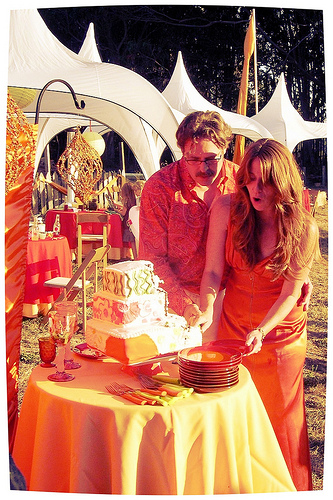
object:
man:
[134, 106, 243, 334]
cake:
[82, 257, 203, 369]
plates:
[176, 347, 244, 366]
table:
[6, 344, 298, 490]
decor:
[0, 134, 67, 181]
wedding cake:
[82, 258, 204, 370]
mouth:
[253, 197, 264, 204]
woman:
[188, 134, 316, 496]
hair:
[229, 138, 322, 278]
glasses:
[179, 153, 223, 170]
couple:
[132, 108, 312, 498]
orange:
[230, 271, 258, 307]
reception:
[5, 43, 230, 323]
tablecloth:
[15, 325, 296, 493]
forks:
[102, 385, 142, 405]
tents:
[0, 3, 177, 184]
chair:
[75, 208, 109, 272]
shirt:
[135, 155, 244, 320]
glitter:
[73, 151, 83, 158]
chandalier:
[55, 131, 102, 205]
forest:
[193, 34, 220, 66]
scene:
[4, 1, 326, 492]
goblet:
[45, 290, 79, 372]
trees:
[99, 10, 137, 46]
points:
[78, 17, 101, 63]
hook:
[29, 73, 86, 127]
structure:
[54, 128, 104, 212]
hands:
[182, 300, 202, 331]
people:
[132, 109, 313, 368]